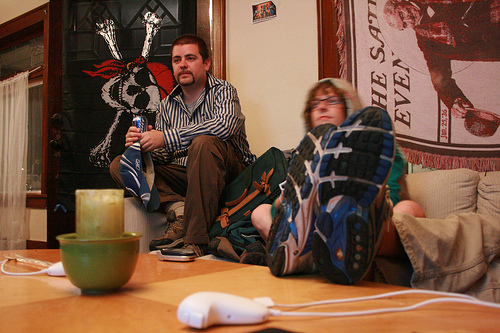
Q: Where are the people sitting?
A: On couch.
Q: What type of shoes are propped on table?
A: Sneakers.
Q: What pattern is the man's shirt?
A: Striped.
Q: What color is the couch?
A: Tan.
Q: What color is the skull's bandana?
A: Red.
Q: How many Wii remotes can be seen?
A: Two.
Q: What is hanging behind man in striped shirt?
A: Pirate flag.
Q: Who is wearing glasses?
A: The man on the right.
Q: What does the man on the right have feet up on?
A: Coffee table.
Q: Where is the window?
A: To the left of the people.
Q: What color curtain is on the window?
A: White.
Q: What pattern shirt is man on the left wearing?
A: Striped.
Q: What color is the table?
A: Brown.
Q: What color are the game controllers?
A: White.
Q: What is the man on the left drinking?
A: Beer.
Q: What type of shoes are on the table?
A: Athletic shoes.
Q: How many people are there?
A: Two.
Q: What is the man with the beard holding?
A: A can and a hat.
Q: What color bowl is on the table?
A: Green.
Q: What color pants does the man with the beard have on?
A: Brown.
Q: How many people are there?
A: Three.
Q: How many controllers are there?
A: Two.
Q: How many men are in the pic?
A: Two.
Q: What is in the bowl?
A: Candle.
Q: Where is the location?
A: Living room.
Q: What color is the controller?
A: White.